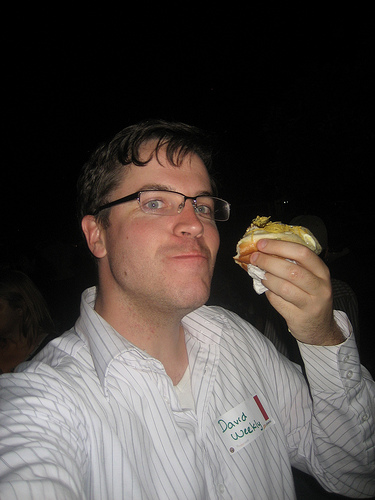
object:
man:
[0, 120, 375, 496]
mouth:
[173, 248, 209, 264]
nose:
[173, 198, 205, 239]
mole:
[124, 270, 127, 276]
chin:
[164, 279, 211, 313]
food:
[232, 215, 323, 272]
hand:
[248, 238, 335, 349]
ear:
[81, 215, 107, 259]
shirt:
[0, 284, 375, 500]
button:
[343, 355, 349, 363]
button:
[347, 370, 353, 378]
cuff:
[294, 309, 361, 390]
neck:
[109, 310, 192, 367]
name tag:
[211, 392, 275, 454]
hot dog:
[230, 217, 324, 251]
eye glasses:
[92, 188, 231, 221]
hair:
[78, 125, 218, 230]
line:
[253, 393, 269, 420]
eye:
[195, 203, 213, 216]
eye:
[142, 198, 170, 210]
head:
[80, 120, 220, 313]